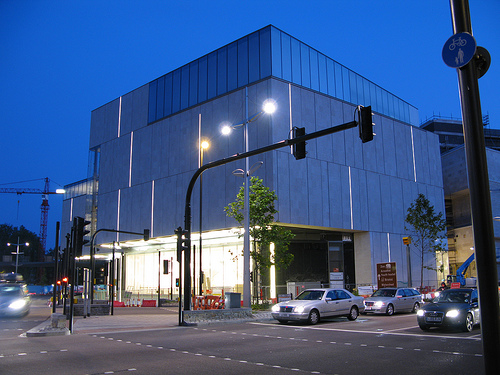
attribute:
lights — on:
[194, 91, 292, 159]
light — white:
[259, 95, 281, 117]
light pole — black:
[181, 105, 376, 312]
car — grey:
[274, 282, 372, 327]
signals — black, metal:
[211, 127, 321, 210]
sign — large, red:
[369, 262, 399, 287]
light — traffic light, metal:
[254, 119, 399, 141]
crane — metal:
[1, 175, 66, 282]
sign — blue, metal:
[431, 23, 475, 68]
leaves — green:
[250, 186, 293, 271]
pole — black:
[460, 83, 485, 339]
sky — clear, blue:
[6, 11, 143, 72]